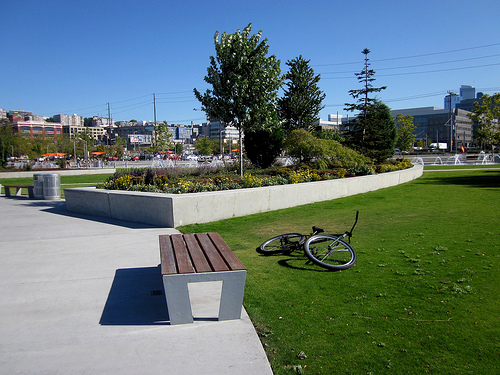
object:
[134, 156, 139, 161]
cars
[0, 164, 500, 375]
floor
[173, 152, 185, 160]
cars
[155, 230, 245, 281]
seat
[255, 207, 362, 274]
bicycle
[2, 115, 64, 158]
buildings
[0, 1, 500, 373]
background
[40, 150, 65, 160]
umbrella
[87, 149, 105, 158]
umbrella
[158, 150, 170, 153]
umbrella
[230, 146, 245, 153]
umbrella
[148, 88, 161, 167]
poles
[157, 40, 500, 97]
electric wires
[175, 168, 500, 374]
grass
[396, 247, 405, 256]
clover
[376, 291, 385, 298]
clover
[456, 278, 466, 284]
clover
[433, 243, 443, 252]
clover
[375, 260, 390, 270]
clover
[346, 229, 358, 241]
handlebar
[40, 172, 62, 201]
garbage can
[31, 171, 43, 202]
garbage can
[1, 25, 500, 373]
park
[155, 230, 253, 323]
bench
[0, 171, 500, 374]
ground